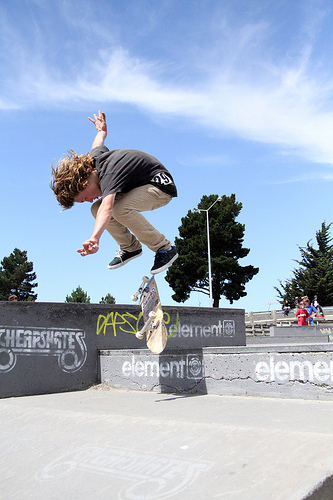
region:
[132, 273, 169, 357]
skateboard in midair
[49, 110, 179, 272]
boy in midair above a skateboard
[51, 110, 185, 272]
boy wearing tan pants and a black shirt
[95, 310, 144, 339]
graffiti on the cement wall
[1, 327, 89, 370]
logo for Cheapskates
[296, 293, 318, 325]
group of people in the background of the skate park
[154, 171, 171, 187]
a number 29 on the boy's shirt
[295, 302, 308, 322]
boy wearing a red and white shirt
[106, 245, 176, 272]
one black shoe with blue laces and one black shoe with white laces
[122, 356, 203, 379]
logo for element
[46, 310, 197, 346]
This is yellow graffiti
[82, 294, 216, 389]
The graffiti is yellow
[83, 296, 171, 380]
The graffiti is paint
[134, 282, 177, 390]
This is a skateboard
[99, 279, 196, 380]
The board is light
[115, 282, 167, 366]
These are the wheels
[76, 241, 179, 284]
These are black shoes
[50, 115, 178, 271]
boy performing a skateboard stunt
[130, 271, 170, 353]
skateboard in the air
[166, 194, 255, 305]
large dark green pine tree in the background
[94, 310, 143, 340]
yellow graffiti on a wall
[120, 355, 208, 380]
skateboard brand on a wall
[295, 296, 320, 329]
people walking on a sidewalk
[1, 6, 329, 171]
white whispy cirrus clouds in the sky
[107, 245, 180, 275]
black skater shoes on the boy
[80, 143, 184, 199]
black shirt on the skater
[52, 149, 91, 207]
shaggy and cirly dark blond hair on the boy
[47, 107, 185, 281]
A skateboarder in the air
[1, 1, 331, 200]
White clouds in the sky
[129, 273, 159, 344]
Wheels on a skateboard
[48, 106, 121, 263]
The guy has two arms raised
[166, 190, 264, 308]
Green leaves on a tree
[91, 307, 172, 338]
Yellow graffiti on a wall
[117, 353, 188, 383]
The word "element" on the wall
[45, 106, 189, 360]
Skateboarder performing a trick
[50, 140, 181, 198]
Guy wearing a black shirt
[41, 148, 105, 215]
Guy has brown hair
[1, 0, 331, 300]
white clouds in sky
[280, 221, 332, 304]
green needles on tree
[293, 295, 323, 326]
people at skate park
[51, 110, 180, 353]
boy jumping above skateboard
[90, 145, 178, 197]
number on black shirt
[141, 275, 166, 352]
bottom of flying skateboard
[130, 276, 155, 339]
four white wheels of skateboard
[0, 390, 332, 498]
surface of skate ramp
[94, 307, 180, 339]
yellow graffiti on wall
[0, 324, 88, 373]
white painted logo on wall